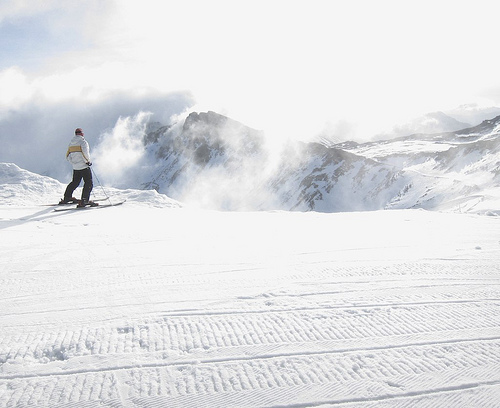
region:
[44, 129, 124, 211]
skier on the edge of a cliff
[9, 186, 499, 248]
edge of a snowy cliff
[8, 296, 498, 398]
tracks in the snow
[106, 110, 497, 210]
fog-covered mountains on the horizon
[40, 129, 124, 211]
skier with a white jacket and black pants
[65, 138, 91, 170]
white jacket with a yellow stripe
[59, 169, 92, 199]
black ski pants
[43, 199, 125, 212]
a pair of snow skis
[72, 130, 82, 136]
red ski helmet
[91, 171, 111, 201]
ski poles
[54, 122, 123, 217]
a man wearing black pants and a white jacket with a yellow stripe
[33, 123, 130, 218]
a skier near the edge of a cliff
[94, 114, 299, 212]
white clouds moving between mountain peaks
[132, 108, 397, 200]
exposed rock and patches of snow on a mountain peak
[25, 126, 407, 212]
ridge between two mountains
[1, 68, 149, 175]
clouds off in the distance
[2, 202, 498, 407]
snow covered surface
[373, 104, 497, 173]
rocks exposed through the snow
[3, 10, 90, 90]
blue sky seen through the clouds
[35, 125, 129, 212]
man has white and yellow jacket on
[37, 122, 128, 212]
man has black pants on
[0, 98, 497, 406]
snow is on ground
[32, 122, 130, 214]
man has skis on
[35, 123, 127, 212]
man has a hat on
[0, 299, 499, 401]
tracks of ski on snow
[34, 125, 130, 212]
man has ski sticks in hand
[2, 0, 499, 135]
sky looks white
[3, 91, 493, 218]
hole in middle of snow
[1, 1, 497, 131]
clouds in sky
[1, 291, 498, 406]
Tracks in the white snow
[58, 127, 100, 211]
Man standing on the snow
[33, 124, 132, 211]
Man in full ski gear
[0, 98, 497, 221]
Steep rocky mountain peaks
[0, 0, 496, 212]
Thick cloudy mist over the peak ranges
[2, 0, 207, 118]
Portion of the visible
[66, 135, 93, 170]
Thick white jacket with a brown wrapping across the chest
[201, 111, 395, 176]
Rimmed edge of the mountain side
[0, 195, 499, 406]
Thick snow on the flat groundd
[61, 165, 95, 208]
Pair of dark pants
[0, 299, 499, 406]
Tracks embedded in white snow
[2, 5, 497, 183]
Dark cloudy overcast sky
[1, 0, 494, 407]
The top of a snowy mountain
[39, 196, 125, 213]
A pair of snow skies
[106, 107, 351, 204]
A misty mountain top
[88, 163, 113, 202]
Skining poles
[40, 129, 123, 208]
A man on a pair of skies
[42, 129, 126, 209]
A man on a pair of snow skies in a white jacket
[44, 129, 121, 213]
A man in a white jacket with a yellow stripe using skies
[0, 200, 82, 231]
The shadow of a man standing on a mountain